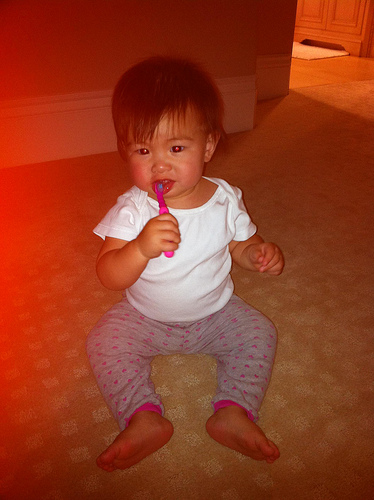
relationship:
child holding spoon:
[84, 55, 284, 473] [147, 174, 175, 245]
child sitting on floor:
[84, 55, 284, 473] [296, 425, 372, 494]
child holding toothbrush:
[84, 55, 284, 473] [143, 181, 184, 222]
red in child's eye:
[173, 145, 180, 150] [165, 140, 192, 159]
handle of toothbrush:
[158, 208, 180, 263] [152, 178, 180, 258]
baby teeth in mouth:
[163, 179, 171, 185] [149, 177, 176, 191]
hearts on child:
[245, 330, 272, 368] [93, 55, 283, 472]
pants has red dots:
[82, 300, 286, 423] [106, 327, 140, 354]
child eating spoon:
[84, 55, 284, 473] [145, 178, 178, 262]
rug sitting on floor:
[301, 36, 356, 62] [294, 58, 341, 79]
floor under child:
[261, 78, 372, 498] [93, 55, 283, 472]